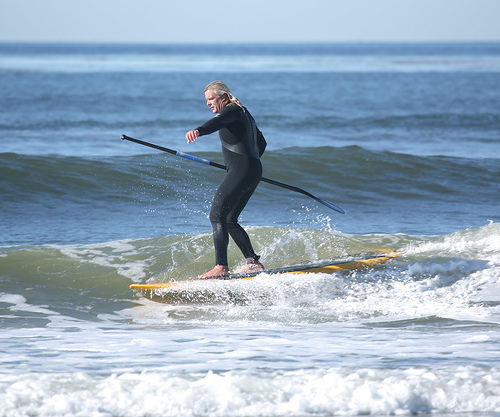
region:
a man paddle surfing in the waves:
[107, 68, 408, 321]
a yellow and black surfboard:
[118, 248, 415, 308]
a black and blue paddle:
[99, 129, 376, 233]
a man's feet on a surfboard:
[190, 252, 283, 281]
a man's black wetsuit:
[152, 103, 300, 285]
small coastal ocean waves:
[1, 36, 498, 406]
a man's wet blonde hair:
[195, 78, 260, 118]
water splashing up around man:
[116, 158, 391, 268]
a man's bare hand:
[181, 123, 205, 146]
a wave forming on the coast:
[0, 143, 499, 221]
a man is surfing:
[99, 59, 381, 306]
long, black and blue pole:
[120, 135, 346, 216]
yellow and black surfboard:
[128, 252, 393, 292]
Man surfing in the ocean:
[185, 79, 267, 276]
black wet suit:
[197, 105, 267, 265]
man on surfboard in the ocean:
[184, 81, 267, 276]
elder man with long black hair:
[185, 80, 269, 275]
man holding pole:
[182, 81, 264, 277]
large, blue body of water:
[0, 67, 497, 415]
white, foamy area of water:
[0, 227, 499, 415]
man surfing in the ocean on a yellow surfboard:
[187, 80, 264, 275]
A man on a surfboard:
[93, 41, 432, 310]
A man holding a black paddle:
[114, 85, 376, 270]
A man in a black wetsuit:
[182, 88, 286, 259]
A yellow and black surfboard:
[132, 251, 402, 303]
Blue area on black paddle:
[168, 148, 230, 171]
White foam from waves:
[4, 254, 466, 379]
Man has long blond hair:
[187, 72, 265, 124]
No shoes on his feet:
[186, 255, 288, 287]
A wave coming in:
[6, 138, 469, 250]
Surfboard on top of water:
[120, 245, 405, 300]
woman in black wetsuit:
[184, 79, 269, 278]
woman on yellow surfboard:
[128, 246, 397, 294]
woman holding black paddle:
[118, 132, 345, 216]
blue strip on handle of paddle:
[174, 150, 213, 165]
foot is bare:
[198, 265, 227, 280]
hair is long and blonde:
[203, 79, 244, 112]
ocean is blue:
[0, 45, 499, 414]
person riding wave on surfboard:
[185, 77, 265, 277]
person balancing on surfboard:
[186, 73, 271, 280]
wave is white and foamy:
[0, 350, 499, 415]